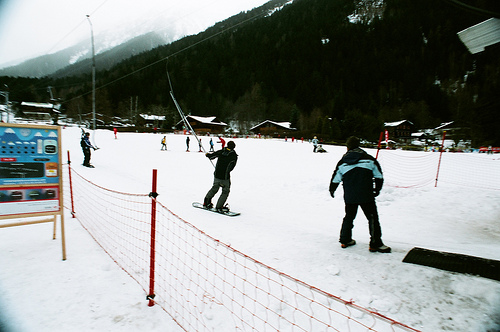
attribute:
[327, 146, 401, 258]
man — wearing, riding, standing, here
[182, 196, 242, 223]
snowboard — here, under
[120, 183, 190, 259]
fence — red, mesh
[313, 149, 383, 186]
coat — blu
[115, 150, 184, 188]
snow — white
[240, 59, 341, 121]
trees — green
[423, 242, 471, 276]
leg — wooden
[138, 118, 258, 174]
people — skiing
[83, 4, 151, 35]
sky — cloudy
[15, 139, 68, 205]
sign — informational, square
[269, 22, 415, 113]
mountain — snow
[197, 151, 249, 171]
top — dark, blue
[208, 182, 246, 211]
pants — grey, black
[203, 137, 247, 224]
snowboarder — holding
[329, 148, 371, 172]
colors — blu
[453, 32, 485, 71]
houses — backgound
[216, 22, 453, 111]
mountains — background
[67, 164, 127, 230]
net — safety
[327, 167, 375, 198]
jacket — black